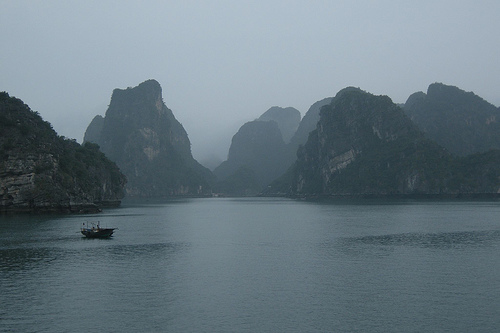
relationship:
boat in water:
[81, 220, 115, 238] [27, 199, 474, 303]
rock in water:
[252, 82, 492, 200] [201, 208, 398, 311]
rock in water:
[265, 77, 485, 229] [164, 207, 473, 332]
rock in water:
[212, 118, 290, 197] [164, 207, 473, 332]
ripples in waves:
[29, 253, 171, 313] [0, 195, 499, 332]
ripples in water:
[29, 253, 171, 313] [149, 207, 493, 324]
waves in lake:
[0, 195, 499, 332] [115, 190, 490, 310]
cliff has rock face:
[0, 87, 60, 211] [17, 148, 50, 215]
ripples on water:
[29, 253, 171, 313] [203, 203, 485, 305]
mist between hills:
[182, 117, 234, 167] [150, 83, 267, 174]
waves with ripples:
[0, 195, 499, 332] [19, 236, 182, 331]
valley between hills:
[192, 143, 224, 171] [103, 66, 306, 204]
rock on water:
[59, 62, 427, 208] [82, 207, 498, 321]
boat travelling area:
[82, 218, 112, 244] [2, 63, 493, 331]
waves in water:
[322, 216, 492, 326] [206, 213, 338, 307]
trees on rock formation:
[3, 90, 128, 195] [0, 91, 129, 214]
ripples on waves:
[331, 215, 496, 299] [0, 195, 499, 332]